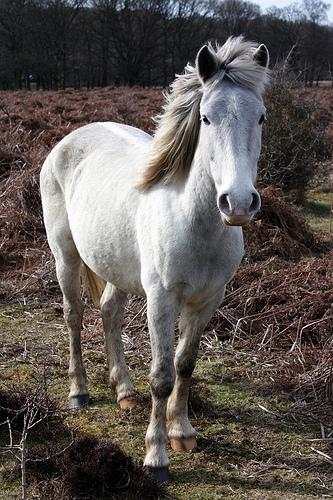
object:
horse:
[39, 36, 272, 483]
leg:
[144, 292, 180, 470]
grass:
[1, 307, 332, 499]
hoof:
[170, 438, 200, 455]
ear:
[197, 47, 217, 80]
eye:
[258, 115, 266, 127]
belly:
[67, 198, 142, 299]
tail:
[82, 265, 107, 310]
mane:
[132, 35, 274, 195]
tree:
[108, 0, 167, 84]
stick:
[1, 394, 75, 499]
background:
[1, 0, 62, 89]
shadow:
[168, 434, 331, 497]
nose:
[219, 190, 262, 216]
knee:
[150, 368, 175, 400]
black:
[146, 467, 169, 486]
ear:
[251, 42, 270, 70]